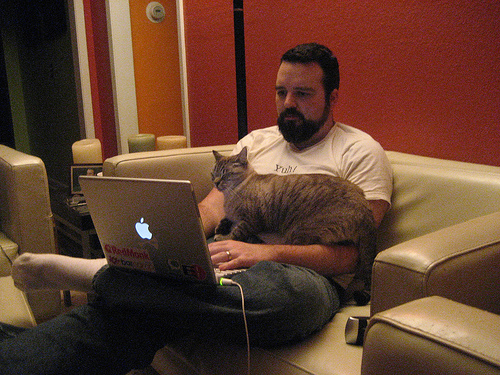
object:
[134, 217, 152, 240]
logo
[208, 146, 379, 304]
cat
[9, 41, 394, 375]
man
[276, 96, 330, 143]
beard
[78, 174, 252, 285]
laptop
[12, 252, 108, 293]
sock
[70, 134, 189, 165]
candles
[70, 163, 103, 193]
picture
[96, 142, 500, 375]
chair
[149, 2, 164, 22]
alarm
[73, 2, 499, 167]
wall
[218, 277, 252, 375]
cord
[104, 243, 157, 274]
sticker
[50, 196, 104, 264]
table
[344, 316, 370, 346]
remote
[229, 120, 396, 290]
shirt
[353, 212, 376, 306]
tail